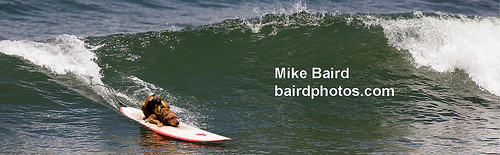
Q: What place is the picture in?
A: It is at the ocean.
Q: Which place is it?
A: It is an ocean.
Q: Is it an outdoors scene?
A: Yes, it is outdoors.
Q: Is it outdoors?
A: Yes, it is outdoors.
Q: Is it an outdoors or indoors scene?
A: It is outdoors.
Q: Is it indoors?
A: No, it is outdoors.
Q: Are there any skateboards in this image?
A: No, there are no skateboards.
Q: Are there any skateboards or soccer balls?
A: No, there are no skateboards or soccer balls.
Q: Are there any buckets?
A: No, there are no buckets.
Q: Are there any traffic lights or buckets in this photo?
A: No, there are no buckets or traffic lights.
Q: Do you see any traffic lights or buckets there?
A: No, there are no buckets or traffic lights.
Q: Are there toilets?
A: No, there are no toilets.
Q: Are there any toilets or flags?
A: No, there are no toilets or flags.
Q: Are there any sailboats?
A: No, there are no sailboats.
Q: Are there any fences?
A: No, there are no fences.